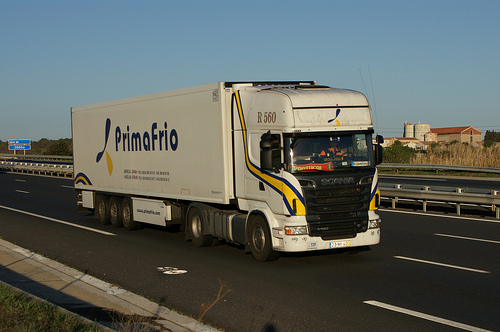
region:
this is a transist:
[60, 79, 377, 239]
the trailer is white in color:
[63, 85, 383, 236]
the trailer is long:
[71, 82, 375, 231]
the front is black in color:
[308, 175, 362, 227]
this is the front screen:
[301, 133, 367, 165]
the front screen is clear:
[299, 132, 364, 166]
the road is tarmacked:
[398, 275, 458, 299]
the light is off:
[286, 225, 309, 235]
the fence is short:
[431, 186, 482, 206]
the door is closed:
[241, 136, 257, 191]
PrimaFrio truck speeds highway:
[57, 80, 387, 257]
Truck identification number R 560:
[237, 100, 288, 170]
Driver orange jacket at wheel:
[317, 136, 356, 161]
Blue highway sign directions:
[0, 134, 66, 179]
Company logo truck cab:
[308, 107, 361, 128]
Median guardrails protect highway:
[384, 161, 497, 247]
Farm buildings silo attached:
[398, 121, 494, 166]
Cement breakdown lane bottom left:
[2, 269, 219, 330]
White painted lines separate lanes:
[385, 206, 498, 327]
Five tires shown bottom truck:
[75, 189, 275, 261]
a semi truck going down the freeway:
[64, 82, 386, 262]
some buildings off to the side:
[402, 119, 480, 146]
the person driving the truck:
[315, 140, 347, 159]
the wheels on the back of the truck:
[96, 197, 133, 227]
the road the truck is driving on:
[4, 171, 498, 326]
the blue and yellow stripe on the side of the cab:
[229, 99, 302, 221]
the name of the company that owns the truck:
[106, 120, 189, 159]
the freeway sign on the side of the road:
[3, 137, 36, 156]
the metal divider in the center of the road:
[390, 186, 499, 217]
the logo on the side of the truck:
[91, 120, 114, 172]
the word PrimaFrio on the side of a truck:
[114, 125, 189, 160]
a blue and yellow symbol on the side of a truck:
[87, 125, 116, 170]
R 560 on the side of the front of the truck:
[255, 105, 282, 125]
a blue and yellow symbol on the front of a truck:
[307, 108, 348, 125]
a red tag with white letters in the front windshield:
[292, 161, 337, 173]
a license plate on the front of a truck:
[323, 240, 350, 249]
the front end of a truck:
[242, 85, 386, 250]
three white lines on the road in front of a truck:
[390, 232, 490, 328]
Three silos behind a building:
[402, 115, 435, 139]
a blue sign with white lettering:
[6, 130, 38, 157]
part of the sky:
[385, 6, 443, 42]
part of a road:
[247, 283, 290, 326]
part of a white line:
[361, 280, 401, 322]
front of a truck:
[292, 167, 376, 299]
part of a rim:
[252, 230, 264, 255]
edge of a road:
[98, 290, 133, 307]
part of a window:
[306, 127, 351, 158]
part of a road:
[239, 252, 286, 289]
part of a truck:
[311, 180, 351, 223]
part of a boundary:
[418, 186, 455, 209]